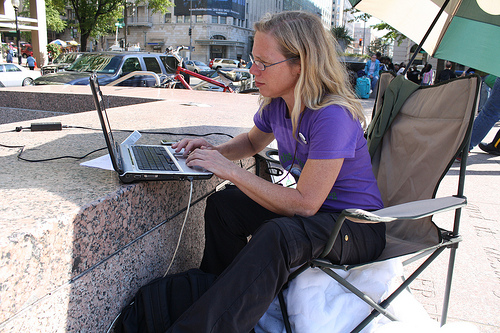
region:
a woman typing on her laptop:
[71, 16, 411, 317]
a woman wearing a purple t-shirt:
[191, 6, 382, 253]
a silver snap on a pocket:
[343, 227, 357, 248]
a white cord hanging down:
[165, 180, 196, 262]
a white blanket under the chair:
[295, 270, 365, 331]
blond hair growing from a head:
[297, 9, 338, 125]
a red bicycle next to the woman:
[167, 41, 232, 91]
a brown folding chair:
[373, 77, 462, 305]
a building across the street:
[179, 4, 240, 35]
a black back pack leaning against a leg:
[130, 277, 208, 331]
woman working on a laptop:
[86, 10, 487, 322]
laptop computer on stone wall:
[83, 65, 215, 184]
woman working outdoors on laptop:
[135, 10, 387, 331]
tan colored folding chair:
[275, 65, 486, 330]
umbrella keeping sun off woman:
[350, 0, 498, 74]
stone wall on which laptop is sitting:
[3, 83, 259, 331]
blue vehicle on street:
[31, 47, 193, 89]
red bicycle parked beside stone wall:
[158, 40, 261, 102]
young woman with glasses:
[173, 7, 394, 329]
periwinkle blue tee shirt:
[249, 96, 385, 212]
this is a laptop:
[81, 76, 209, 178]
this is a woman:
[180, 7, 370, 282]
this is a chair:
[400, 80, 460, 320]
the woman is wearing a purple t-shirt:
[247, 100, 368, 205]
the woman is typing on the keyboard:
[170, 126, 210, 176]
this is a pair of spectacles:
[246, 50, 299, 73]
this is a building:
[187, 2, 239, 54]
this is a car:
[53, 54, 164, 76]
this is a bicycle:
[166, 45, 230, 90]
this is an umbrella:
[356, 0, 498, 67]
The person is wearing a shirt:
[243, 31, 347, 262]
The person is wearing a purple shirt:
[237, 81, 384, 249]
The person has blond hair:
[247, 26, 367, 111]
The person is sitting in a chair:
[391, 61, 485, 226]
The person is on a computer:
[82, 57, 222, 209]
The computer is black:
[82, 54, 227, 208]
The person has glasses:
[249, 45, 284, 91]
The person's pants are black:
[197, 197, 355, 314]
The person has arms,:
[183, 136, 320, 221]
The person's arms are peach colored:
[188, 151, 334, 215]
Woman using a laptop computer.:
[89, 13, 389, 331]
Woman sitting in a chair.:
[115, 0, 497, 332]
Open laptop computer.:
[87, 68, 215, 181]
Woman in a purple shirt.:
[168, 13, 386, 332]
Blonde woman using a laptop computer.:
[87, 9, 387, 331]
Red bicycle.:
[167, 43, 258, 95]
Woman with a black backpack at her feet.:
[113, 5, 388, 332]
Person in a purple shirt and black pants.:
[157, 10, 386, 332]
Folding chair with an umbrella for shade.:
[275, 0, 498, 332]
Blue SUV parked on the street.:
[33, 49, 192, 89]